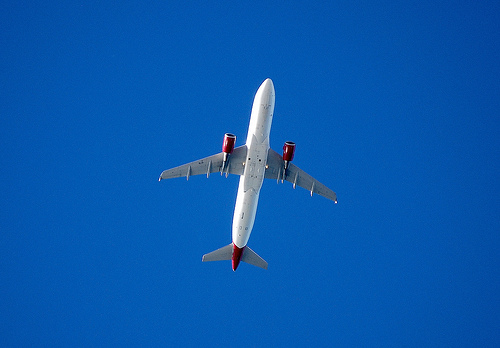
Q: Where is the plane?
A: Sky.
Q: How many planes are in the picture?
A: One.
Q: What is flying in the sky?
A: A plane.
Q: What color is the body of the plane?
A: White.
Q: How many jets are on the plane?
A: Two.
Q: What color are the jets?
A: Red.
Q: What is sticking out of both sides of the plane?
A: Wings.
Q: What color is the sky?
A: Blue.